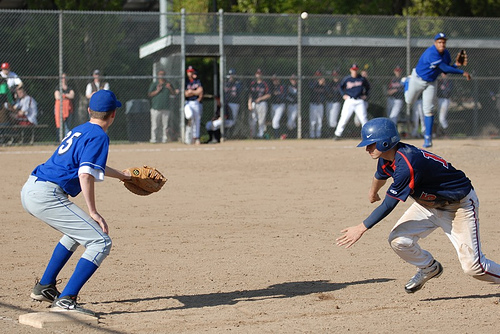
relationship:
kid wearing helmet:
[337, 117, 500, 295] [359, 117, 401, 150]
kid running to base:
[488, 117, 498, 243] [19, 307, 100, 328]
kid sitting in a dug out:
[197, 55, 332, 139] [130, 25, 460, 124]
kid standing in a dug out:
[244, 71, 266, 113] [145, 33, 471, 131]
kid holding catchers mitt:
[12, 88, 159, 321] [107, 122, 209, 222]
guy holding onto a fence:
[146, 67, 176, 142] [3, 11, 498, 141]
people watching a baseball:
[0, 53, 137, 134] [4, 16, 497, 326]